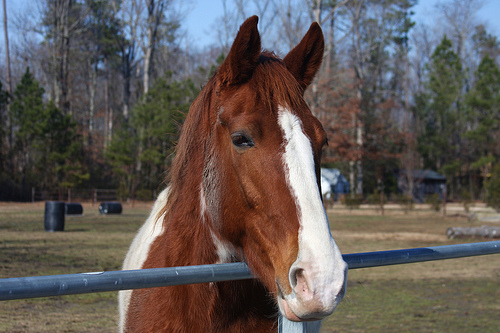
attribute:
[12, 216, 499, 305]
rail — grey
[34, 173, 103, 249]
barrel — black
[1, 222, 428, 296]
railing — metal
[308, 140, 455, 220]
house — blue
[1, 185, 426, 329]
field — grassy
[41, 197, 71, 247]
barrel — black, large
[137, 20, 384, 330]
horse — brown, white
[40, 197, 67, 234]
barrel — black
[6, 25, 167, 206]
tree forest — large, tall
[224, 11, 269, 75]
ear — pointy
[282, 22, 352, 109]
ear — pointy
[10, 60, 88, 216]
tree — large, green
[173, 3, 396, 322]
horse — brown, white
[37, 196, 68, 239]
barrel — black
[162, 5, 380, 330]
horse — brown, white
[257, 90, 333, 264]
blaze — white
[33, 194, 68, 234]
barrel — black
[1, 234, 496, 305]
pole — gray, metal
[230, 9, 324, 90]
ears — brown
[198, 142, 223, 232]
fur — dirty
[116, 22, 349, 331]
building — small, brown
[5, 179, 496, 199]
fence — wooden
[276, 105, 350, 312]
blaze — white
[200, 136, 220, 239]
dirt — died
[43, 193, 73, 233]
barrel — black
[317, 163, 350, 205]
house — white